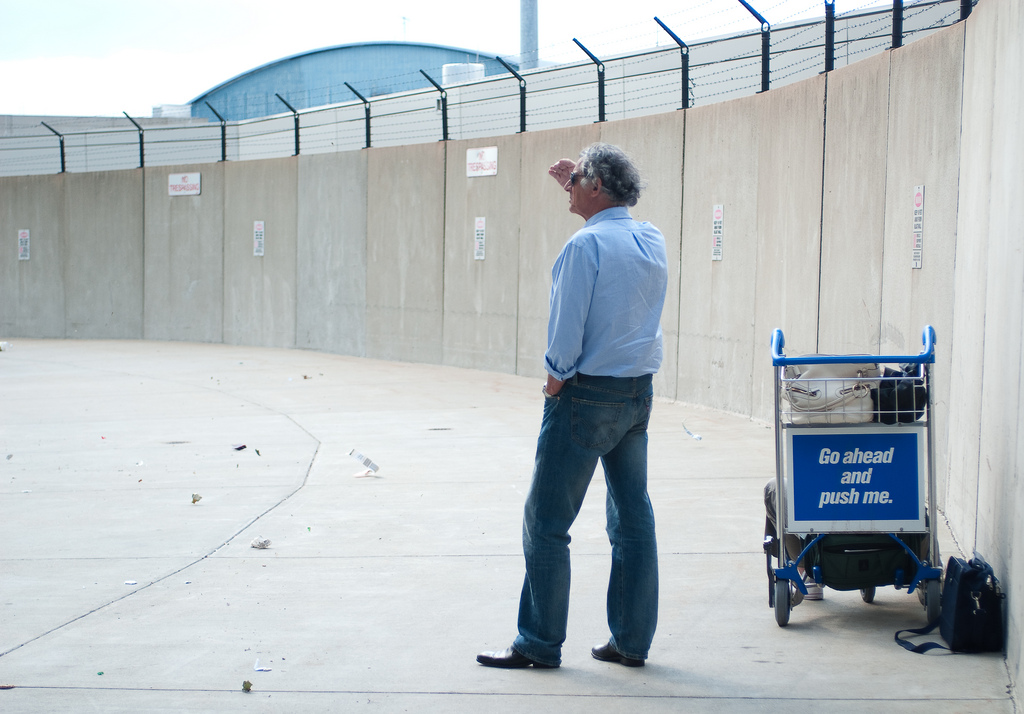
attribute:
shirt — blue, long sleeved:
[543, 203, 680, 384]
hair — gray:
[576, 142, 643, 216]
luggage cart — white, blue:
[762, 324, 949, 635]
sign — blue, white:
[777, 417, 926, 532]